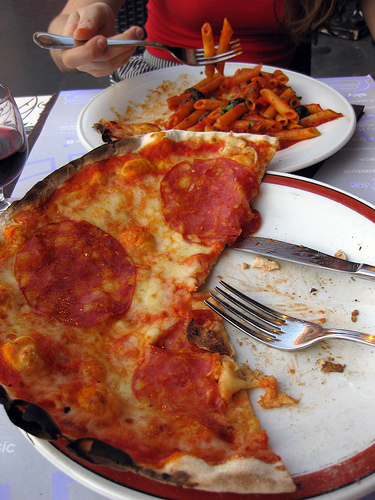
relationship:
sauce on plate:
[194, 297, 213, 315] [292, 190, 324, 243]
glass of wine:
[1, 90, 27, 209] [0, 97, 28, 183]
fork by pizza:
[202, 275, 373, 358] [4, 147, 304, 497]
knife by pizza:
[227, 234, 375, 281] [4, 147, 304, 497]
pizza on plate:
[4, 147, 304, 497] [257, 163, 373, 499]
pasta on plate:
[167, 63, 342, 149] [74, 55, 367, 179]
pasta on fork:
[165, 17, 341, 150] [32, 30, 241, 66]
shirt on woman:
[145, 1, 311, 76] [48, 0, 374, 85]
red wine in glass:
[0, 127, 29, 199] [0, 70, 35, 211]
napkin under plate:
[299, 101, 365, 180] [74, 55, 367, 179]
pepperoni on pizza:
[15, 218, 151, 318] [0, 117, 316, 417]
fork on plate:
[33, 31, 243, 67] [240, 158, 374, 494]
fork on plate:
[203, 279, 375, 353] [62, 58, 364, 175]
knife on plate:
[227, 234, 375, 281] [0, 168, 375, 500]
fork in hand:
[24, 19, 248, 75] [40, 4, 153, 74]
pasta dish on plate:
[147, 22, 339, 151] [74, 42, 363, 228]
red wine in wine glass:
[2, 124, 30, 191] [2, 81, 29, 212]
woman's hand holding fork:
[59, 0, 145, 79] [33, 31, 243, 67]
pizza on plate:
[4, 147, 304, 497] [0, 168, 375, 500]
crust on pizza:
[0, 128, 238, 492] [4, 147, 304, 497]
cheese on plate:
[20, 110, 243, 487] [72, 55, 354, 196]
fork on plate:
[203, 279, 375, 353] [265, 168, 372, 249]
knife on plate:
[227, 227, 374, 285] [265, 168, 372, 249]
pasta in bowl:
[168, 62, 330, 133] [67, 44, 361, 187]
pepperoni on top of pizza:
[160, 158, 255, 245] [4, 147, 304, 497]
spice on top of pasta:
[223, 98, 237, 110] [164, 20, 342, 138]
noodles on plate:
[159, 56, 343, 158] [74, 55, 367, 179]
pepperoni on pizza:
[13, 218, 137, 330] [25, 152, 164, 430]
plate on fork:
[0, 168, 375, 500] [184, 273, 374, 369]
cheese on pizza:
[103, 287, 173, 348] [11, 191, 334, 487]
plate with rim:
[279, 175, 369, 236] [276, 447, 359, 493]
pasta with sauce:
[200, 17, 234, 77] [107, 65, 343, 148]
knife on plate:
[227, 234, 375, 281] [269, 156, 349, 223]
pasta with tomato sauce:
[165, 17, 341, 150] [216, 90, 280, 113]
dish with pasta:
[73, 58, 355, 175] [155, 16, 342, 143]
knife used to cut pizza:
[227, 234, 375, 281] [2, 105, 304, 498]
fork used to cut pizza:
[203, 279, 375, 353] [2, 105, 304, 498]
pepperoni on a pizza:
[160, 158, 255, 245] [6, 128, 352, 498]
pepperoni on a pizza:
[18, 222, 136, 324] [6, 128, 352, 498]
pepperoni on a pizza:
[133, 315, 225, 430] [6, 128, 352, 498]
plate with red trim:
[0, 168, 375, 500] [262, 169, 373, 224]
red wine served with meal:
[0, 127, 29, 199] [4, 57, 362, 498]